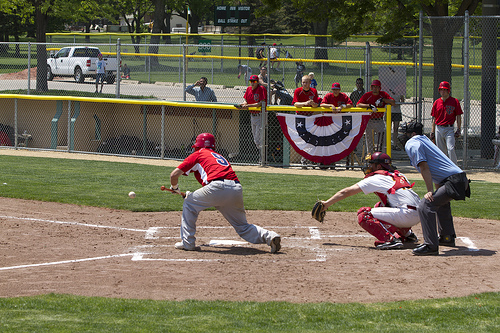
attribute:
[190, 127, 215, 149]
helmet. — red 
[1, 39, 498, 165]
fence — chain link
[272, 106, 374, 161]
banner — red white and blue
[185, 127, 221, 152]
helmet — red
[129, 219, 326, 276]
lines — white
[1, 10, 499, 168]
fence — metal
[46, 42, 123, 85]
truck — white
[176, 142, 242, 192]
jersey — red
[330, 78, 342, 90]
ball cap — red , blue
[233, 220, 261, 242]
knee — bent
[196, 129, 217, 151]
helmet — red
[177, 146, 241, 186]
shirt — red and blue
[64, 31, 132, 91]
truck — white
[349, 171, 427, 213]
shirt — white